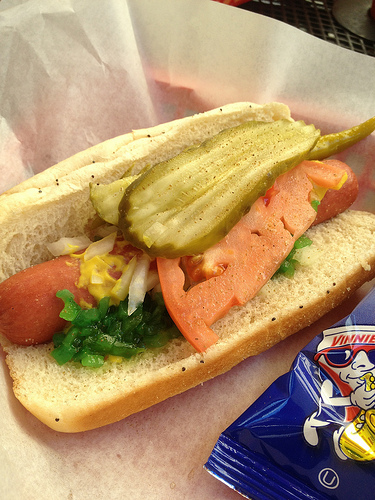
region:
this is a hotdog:
[4, 112, 372, 417]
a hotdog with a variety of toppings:
[1, 82, 370, 440]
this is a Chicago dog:
[0, 73, 373, 421]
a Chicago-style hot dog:
[1, 61, 369, 448]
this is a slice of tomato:
[138, 141, 373, 349]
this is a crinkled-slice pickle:
[93, 106, 344, 262]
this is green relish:
[44, 292, 185, 367]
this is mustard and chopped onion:
[56, 220, 152, 315]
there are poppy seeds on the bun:
[3, 91, 373, 408]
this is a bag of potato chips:
[173, 278, 373, 494]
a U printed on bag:
[315, 463, 346, 491]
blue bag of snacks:
[200, 292, 373, 498]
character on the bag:
[299, 325, 373, 443]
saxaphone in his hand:
[342, 370, 373, 468]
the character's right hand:
[348, 386, 373, 410]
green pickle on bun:
[114, 85, 320, 255]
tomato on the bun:
[158, 160, 337, 356]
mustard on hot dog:
[80, 259, 112, 276]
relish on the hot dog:
[62, 317, 139, 361]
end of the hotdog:
[0, 265, 56, 344]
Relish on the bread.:
[53, 289, 174, 368]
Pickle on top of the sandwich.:
[117, 126, 374, 251]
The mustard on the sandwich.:
[79, 251, 131, 306]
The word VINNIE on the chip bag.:
[329, 333, 374, 346]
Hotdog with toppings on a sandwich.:
[1, 85, 374, 433]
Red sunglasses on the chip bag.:
[318, 342, 373, 359]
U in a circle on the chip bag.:
[317, 459, 341, 490]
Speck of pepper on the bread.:
[52, 411, 62, 430]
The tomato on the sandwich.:
[151, 164, 361, 338]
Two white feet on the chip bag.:
[302, 417, 354, 459]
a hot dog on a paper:
[76, 50, 371, 372]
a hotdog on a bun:
[27, 106, 283, 417]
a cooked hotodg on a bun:
[49, 125, 369, 387]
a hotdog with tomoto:
[18, 169, 304, 449]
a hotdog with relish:
[37, 178, 328, 404]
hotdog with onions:
[52, 163, 275, 354]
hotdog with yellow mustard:
[41, 173, 222, 483]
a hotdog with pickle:
[54, 162, 300, 329]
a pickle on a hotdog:
[22, 168, 297, 417]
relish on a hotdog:
[48, 207, 272, 414]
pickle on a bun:
[102, 111, 312, 220]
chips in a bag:
[222, 375, 329, 495]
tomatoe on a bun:
[244, 203, 312, 287]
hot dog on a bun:
[8, 258, 57, 313]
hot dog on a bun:
[61, 133, 361, 293]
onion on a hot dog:
[81, 240, 111, 258]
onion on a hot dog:
[131, 261, 150, 308]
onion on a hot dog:
[55, 225, 81, 252]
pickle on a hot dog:
[88, 172, 119, 213]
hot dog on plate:
[39, 144, 345, 348]